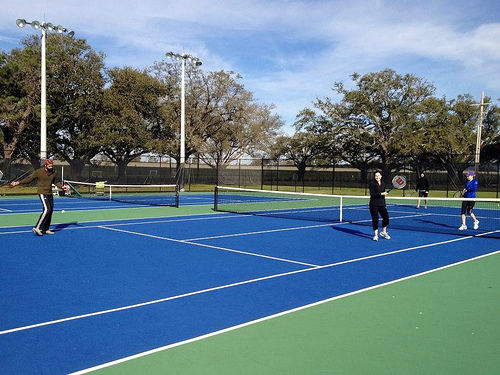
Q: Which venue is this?
A: This is a park.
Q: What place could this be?
A: It is a park.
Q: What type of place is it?
A: It is a park.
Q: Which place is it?
A: It is a park.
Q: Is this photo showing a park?
A: Yes, it is showing a park.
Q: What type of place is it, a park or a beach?
A: It is a park.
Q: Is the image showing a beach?
A: No, the picture is showing a park.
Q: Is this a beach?
A: No, it is a park.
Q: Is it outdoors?
A: Yes, it is outdoors.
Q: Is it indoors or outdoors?
A: It is outdoors.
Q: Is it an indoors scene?
A: No, it is outdoors.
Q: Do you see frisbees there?
A: No, there are no frisbees.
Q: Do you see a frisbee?
A: No, there are no frisbees.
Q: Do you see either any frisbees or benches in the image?
A: No, there are no frisbees or benches.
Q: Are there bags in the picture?
A: No, there are no bags.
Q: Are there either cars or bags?
A: No, there are no bags or cars.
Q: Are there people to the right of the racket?
A: Yes, there is a person to the right of the racket.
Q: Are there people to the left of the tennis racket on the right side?
A: No, the person is to the right of the racket.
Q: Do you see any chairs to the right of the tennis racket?
A: No, there is a person to the right of the tennis racket.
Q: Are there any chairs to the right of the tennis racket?
A: No, there is a person to the right of the tennis racket.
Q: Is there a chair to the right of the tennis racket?
A: No, there is a person to the right of the tennis racket.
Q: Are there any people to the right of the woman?
A: Yes, there is a person to the right of the woman.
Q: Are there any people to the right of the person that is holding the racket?
A: Yes, there is a person to the right of the woman.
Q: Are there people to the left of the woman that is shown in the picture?
A: No, the person is to the right of the woman.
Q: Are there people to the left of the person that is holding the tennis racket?
A: No, the person is to the right of the woman.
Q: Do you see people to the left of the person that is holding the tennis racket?
A: No, the person is to the right of the woman.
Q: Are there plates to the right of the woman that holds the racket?
A: No, there is a person to the right of the woman.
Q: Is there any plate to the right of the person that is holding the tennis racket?
A: No, there is a person to the right of the woman.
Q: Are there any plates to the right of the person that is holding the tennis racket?
A: No, there is a person to the right of the woman.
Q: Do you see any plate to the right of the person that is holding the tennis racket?
A: No, there is a person to the right of the woman.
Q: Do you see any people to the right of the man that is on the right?
A: Yes, there is a person to the right of the man.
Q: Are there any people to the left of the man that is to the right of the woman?
A: No, the person is to the right of the man.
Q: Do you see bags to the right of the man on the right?
A: No, there is a person to the right of the man.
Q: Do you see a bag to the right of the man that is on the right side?
A: No, there is a person to the right of the man.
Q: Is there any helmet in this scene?
A: No, there are no helmets.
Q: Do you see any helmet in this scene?
A: No, there are no helmets.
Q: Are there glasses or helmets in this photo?
A: No, there are no helmets or glasses.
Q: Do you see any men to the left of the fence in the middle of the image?
A: Yes, there is a man to the left of the fence.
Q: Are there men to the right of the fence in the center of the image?
A: No, the man is to the left of the fence.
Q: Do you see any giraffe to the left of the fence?
A: No, there is a man to the left of the fence.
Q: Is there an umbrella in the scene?
A: No, there are no umbrellas.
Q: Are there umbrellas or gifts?
A: No, there are no umbrellas or gifts.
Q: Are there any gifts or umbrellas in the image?
A: No, there are no umbrellas or gifts.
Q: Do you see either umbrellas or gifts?
A: No, there are no umbrellas or gifts.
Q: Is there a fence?
A: Yes, there is a fence.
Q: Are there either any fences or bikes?
A: Yes, there is a fence.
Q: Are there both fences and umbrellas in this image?
A: No, there is a fence but no umbrellas.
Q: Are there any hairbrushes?
A: No, there are no hairbrushes.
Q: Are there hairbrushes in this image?
A: No, there are no hairbrushes.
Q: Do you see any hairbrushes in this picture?
A: No, there are no hairbrushes.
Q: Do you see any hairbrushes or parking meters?
A: No, there are no hairbrushes or parking meters.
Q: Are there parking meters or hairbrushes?
A: No, there are no hairbrushes or parking meters.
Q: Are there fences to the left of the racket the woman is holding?
A: Yes, there is a fence to the left of the racket.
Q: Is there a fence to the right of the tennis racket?
A: No, the fence is to the left of the tennis racket.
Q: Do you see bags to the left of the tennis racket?
A: No, there is a fence to the left of the tennis racket.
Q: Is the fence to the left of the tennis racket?
A: Yes, the fence is to the left of the tennis racket.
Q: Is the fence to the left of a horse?
A: No, the fence is to the left of the tennis racket.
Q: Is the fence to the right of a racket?
A: No, the fence is to the left of a racket.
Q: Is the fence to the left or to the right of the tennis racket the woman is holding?
A: The fence is to the left of the racket.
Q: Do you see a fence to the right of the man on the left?
A: Yes, there is a fence to the right of the man.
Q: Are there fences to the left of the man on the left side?
A: No, the fence is to the right of the man.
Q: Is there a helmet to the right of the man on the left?
A: No, there is a fence to the right of the man.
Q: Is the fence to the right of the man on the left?
A: Yes, the fence is to the right of the man.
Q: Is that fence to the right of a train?
A: No, the fence is to the right of the man.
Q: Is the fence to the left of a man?
A: No, the fence is to the right of a man.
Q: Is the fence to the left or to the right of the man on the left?
A: The fence is to the right of the man.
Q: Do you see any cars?
A: No, there are no cars.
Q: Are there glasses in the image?
A: No, there are no glasses.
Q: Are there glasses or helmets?
A: No, there are no glasses or helmets.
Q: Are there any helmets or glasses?
A: No, there are no glasses or helmets.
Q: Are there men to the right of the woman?
A: Yes, there is a man to the right of the woman.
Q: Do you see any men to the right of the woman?
A: Yes, there is a man to the right of the woman.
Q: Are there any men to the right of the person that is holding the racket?
A: Yes, there is a man to the right of the woman.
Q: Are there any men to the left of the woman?
A: No, the man is to the right of the woman.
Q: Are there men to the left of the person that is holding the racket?
A: No, the man is to the right of the woman.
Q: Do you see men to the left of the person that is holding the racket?
A: No, the man is to the right of the woman.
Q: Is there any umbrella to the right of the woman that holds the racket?
A: No, there is a man to the right of the woman.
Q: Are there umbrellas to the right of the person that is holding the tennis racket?
A: No, there is a man to the right of the woman.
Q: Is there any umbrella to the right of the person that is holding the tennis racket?
A: No, there is a man to the right of the woman.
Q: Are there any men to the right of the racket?
A: Yes, there is a man to the right of the racket.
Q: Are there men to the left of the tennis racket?
A: No, the man is to the right of the tennis racket.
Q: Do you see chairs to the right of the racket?
A: No, there is a man to the right of the racket.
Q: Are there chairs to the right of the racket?
A: No, there is a man to the right of the racket.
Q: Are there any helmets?
A: No, there are no helmets.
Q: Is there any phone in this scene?
A: Yes, there is a phone.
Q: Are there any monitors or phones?
A: Yes, there is a phone.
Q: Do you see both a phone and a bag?
A: No, there is a phone but no bags.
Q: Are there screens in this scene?
A: No, there are no screens.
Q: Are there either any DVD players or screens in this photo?
A: No, there are no screens or DVD players.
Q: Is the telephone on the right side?
A: Yes, the telephone is on the right of the image.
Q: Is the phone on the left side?
A: No, the phone is on the right of the image.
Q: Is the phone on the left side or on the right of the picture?
A: The phone is on the right of the image.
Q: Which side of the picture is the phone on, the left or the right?
A: The phone is on the right of the image.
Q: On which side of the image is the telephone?
A: The telephone is on the right of the image.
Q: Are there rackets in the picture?
A: Yes, there is a racket.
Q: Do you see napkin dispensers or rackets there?
A: Yes, there is a racket.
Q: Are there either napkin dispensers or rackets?
A: Yes, there is a racket.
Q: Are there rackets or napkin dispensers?
A: Yes, there is a racket.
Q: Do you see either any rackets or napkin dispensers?
A: Yes, there is a racket.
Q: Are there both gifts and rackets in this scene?
A: No, there is a racket but no gifts.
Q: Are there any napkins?
A: No, there are no napkins.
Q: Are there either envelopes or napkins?
A: No, there are no napkins or envelopes.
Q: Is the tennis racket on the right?
A: Yes, the tennis racket is on the right of the image.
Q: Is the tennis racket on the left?
A: No, the tennis racket is on the right of the image.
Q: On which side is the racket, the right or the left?
A: The racket is on the right of the image.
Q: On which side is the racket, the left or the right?
A: The racket is on the right of the image.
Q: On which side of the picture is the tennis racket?
A: The tennis racket is on the right of the image.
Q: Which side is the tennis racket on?
A: The tennis racket is on the right of the image.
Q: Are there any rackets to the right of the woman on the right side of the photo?
A: Yes, there is a racket to the right of the woman.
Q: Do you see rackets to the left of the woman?
A: No, the racket is to the right of the woman.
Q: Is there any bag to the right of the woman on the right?
A: No, there is a racket to the right of the woman.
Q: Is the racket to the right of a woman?
A: Yes, the racket is to the right of a woman.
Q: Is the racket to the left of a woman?
A: No, the racket is to the right of a woman.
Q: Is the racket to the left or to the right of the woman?
A: The racket is to the right of the woman.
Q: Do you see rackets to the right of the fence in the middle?
A: Yes, there is a racket to the right of the fence.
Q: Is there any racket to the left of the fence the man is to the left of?
A: No, the racket is to the right of the fence.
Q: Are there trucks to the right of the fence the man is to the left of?
A: No, there is a racket to the right of the fence.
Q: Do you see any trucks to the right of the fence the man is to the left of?
A: No, there is a racket to the right of the fence.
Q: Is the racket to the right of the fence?
A: Yes, the racket is to the right of the fence.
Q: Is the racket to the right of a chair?
A: No, the racket is to the right of the fence.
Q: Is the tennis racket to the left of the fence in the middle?
A: No, the tennis racket is to the right of the fence.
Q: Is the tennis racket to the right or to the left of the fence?
A: The tennis racket is to the right of the fence.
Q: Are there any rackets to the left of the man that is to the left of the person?
A: Yes, there is a racket to the left of the man.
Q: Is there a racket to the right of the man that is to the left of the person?
A: No, the racket is to the left of the man.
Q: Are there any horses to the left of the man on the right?
A: No, there is a racket to the left of the man.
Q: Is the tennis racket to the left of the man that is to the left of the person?
A: Yes, the tennis racket is to the left of the man.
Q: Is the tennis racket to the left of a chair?
A: No, the tennis racket is to the left of the man.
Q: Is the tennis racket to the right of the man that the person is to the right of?
A: No, the tennis racket is to the left of the man.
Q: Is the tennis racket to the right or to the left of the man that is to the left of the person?
A: The tennis racket is to the left of the man.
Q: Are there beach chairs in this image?
A: No, there are no beach chairs.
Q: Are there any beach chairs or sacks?
A: No, there are no beach chairs or sacks.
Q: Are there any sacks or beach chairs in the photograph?
A: No, there are no beach chairs or sacks.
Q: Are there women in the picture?
A: Yes, there is a woman.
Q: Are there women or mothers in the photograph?
A: Yes, there is a woman.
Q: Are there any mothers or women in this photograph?
A: Yes, there is a woman.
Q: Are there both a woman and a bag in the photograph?
A: No, there is a woman but no bags.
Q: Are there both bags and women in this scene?
A: No, there is a woman but no bags.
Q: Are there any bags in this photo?
A: No, there are no bags.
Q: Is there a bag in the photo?
A: No, there are no bags.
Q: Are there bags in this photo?
A: No, there are no bags.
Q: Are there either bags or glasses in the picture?
A: No, there are no bags or glasses.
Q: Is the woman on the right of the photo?
A: Yes, the woman is on the right of the image.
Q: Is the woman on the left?
A: No, the woman is on the right of the image.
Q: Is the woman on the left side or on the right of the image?
A: The woman is on the right of the image.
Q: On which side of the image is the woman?
A: The woman is on the right of the image.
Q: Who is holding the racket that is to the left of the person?
A: The woman is holding the racket.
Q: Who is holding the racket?
A: The woman is holding the racket.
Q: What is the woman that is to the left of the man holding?
A: The woman is holding the racket.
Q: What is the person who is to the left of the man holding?
A: The woman is holding the racket.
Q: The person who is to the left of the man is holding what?
A: The woman is holding the racket.